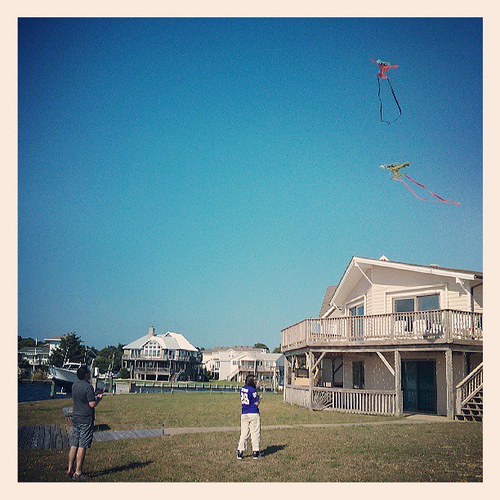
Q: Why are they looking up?
A: Flying kites.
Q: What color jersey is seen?
A: Blue.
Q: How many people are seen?
A: Two.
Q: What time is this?
A: Daytime.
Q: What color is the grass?
A: Green.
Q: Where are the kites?
A: In the air.